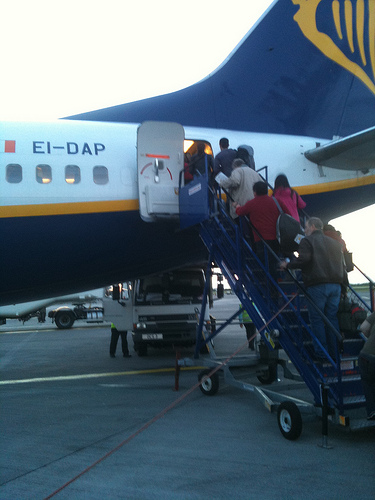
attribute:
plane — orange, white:
[0, 0, 374, 308]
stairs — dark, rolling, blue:
[180, 158, 373, 439]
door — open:
[133, 118, 187, 223]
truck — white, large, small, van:
[130, 270, 216, 353]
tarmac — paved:
[2, 289, 375, 498]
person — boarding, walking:
[238, 178, 291, 262]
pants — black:
[106, 320, 132, 360]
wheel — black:
[274, 400, 306, 442]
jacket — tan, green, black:
[288, 233, 352, 286]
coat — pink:
[270, 183, 308, 221]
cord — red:
[41, 287, 301, 498]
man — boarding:
[283, 218, 348, 361]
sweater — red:
[238, 196, 284, 242]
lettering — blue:
[30, 138, 106, 158]